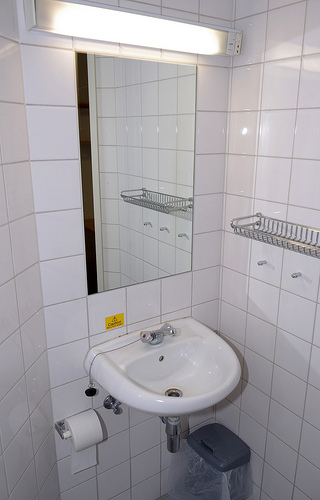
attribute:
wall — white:
[0, 1, 320, 497]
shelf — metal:
[231, 213, 319, 258]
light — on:
[23, 0, 242, 58]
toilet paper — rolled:
[58, 405, 106, 474]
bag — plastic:
[166, 443, 253, 498]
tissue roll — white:
[62, 406, 105, 476]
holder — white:
[21, 2, 248, 63]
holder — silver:
[48, 406, 121, 459]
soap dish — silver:
[227, 211, 319, 258]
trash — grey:
[168, 422, 253, 498]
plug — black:
[81, 385, 99, 401]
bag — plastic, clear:
[166, 448, 260, 498]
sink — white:
[90, 333, 228, 411]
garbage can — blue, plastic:
[183, 421, 252, 498]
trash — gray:
[185, 422, 250, 471]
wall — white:
[12, 50, 261, 311]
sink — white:
[84, 310, 269, 405]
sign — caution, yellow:
[103, 311, 126, 331]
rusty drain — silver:
[164, 385, 184, 396]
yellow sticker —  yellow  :
[104, 313, 125, 329]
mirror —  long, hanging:
[93, 206, 190, 270]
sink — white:
[120, 328, 250, 402]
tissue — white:
[59, 406, 116, 474]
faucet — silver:
[137, 316, 186, 355]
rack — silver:
[227, 206, 316, 275]